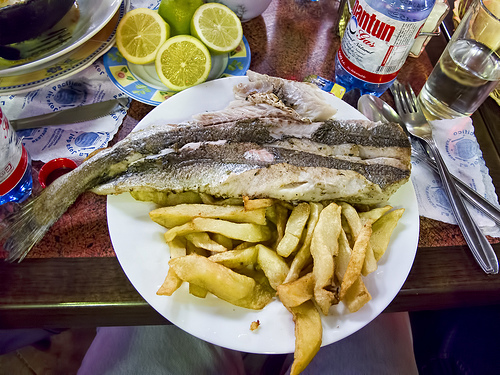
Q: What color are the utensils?
A: Silver.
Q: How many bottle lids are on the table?
A: One.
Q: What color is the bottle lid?
A: Red.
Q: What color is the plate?
A: White.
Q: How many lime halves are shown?
A: Three.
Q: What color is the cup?
A: Clear.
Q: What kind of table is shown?
A: Wood.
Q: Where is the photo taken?
A: At a restaurant.